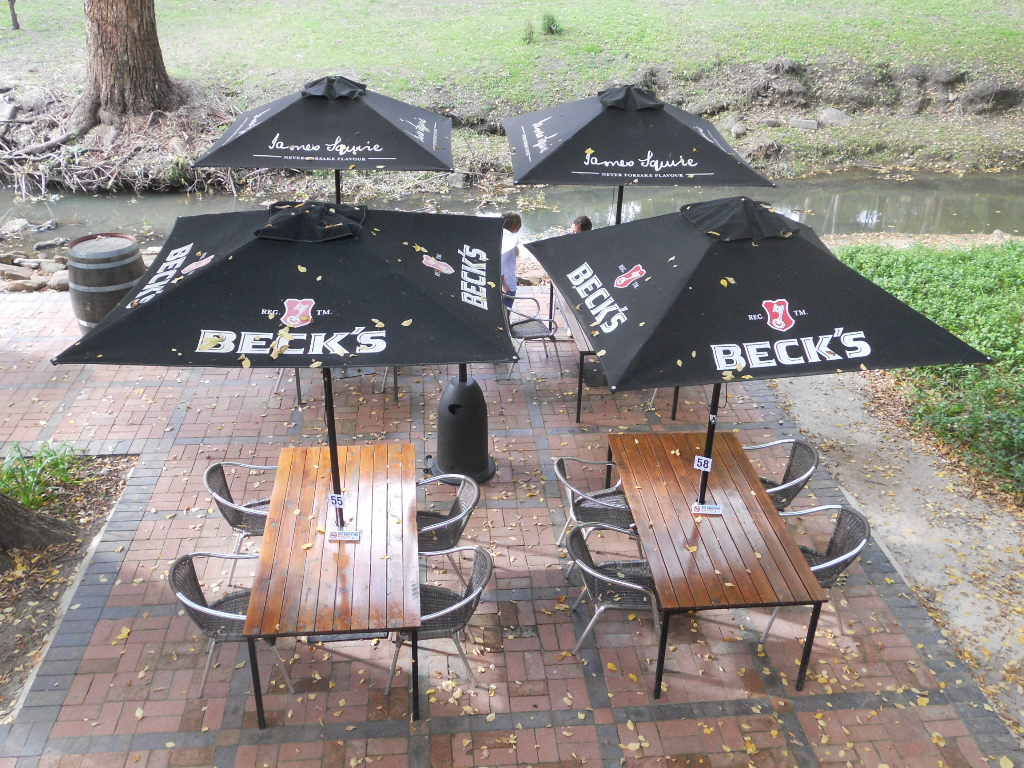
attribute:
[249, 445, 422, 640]
table top — brown, wooden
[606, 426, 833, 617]
table top — brown, wooden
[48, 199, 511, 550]
umbrella — black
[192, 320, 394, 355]
letters — white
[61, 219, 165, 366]
barrel — old fashioned, wooden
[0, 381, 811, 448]
creek — narrow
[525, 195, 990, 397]
umbrella — black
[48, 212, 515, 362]
umbrella — black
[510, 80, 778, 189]
umbrella — black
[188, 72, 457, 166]
umbrella — black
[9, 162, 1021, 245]
creek — small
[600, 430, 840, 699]
table — wooden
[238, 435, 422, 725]
table — wooden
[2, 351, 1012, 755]
bricks — red and gray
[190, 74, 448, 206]
umbrellas — four, black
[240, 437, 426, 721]
tables — wooden, plank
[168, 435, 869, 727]
chairs — eight, gray, silver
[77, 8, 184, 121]
trunk — round, brown, tree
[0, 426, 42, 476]
leaves — covering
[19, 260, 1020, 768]
ground — covered, flat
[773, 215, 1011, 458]
grass — green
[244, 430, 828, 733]
tables — wooden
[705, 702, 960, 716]
leaves — many yellow 